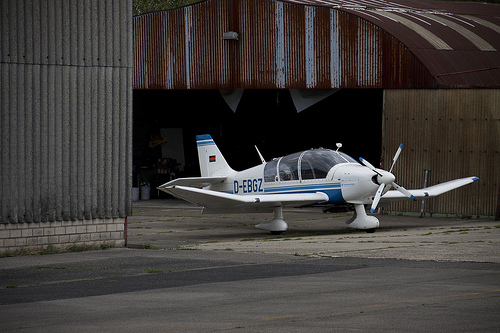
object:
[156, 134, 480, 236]
plane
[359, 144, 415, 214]
propeller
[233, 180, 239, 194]
d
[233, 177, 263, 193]
d-e8gz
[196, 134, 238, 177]
tail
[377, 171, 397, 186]
nose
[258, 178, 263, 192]
z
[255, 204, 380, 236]
landing gear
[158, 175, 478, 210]
wings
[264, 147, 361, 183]
windows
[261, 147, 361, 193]
cockpit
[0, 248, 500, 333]
concrete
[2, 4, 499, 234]
hangar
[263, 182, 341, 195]
stripe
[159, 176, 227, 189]
vertical stabilizer